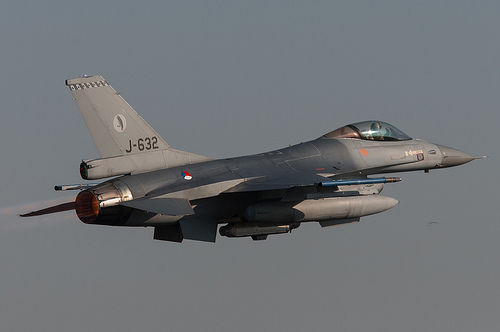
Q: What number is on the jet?
A: J-632.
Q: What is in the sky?
A: A jet.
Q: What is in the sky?
A: A plane.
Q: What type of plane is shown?
A: A military plane.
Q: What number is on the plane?
A: J-632.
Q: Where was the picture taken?
A: The sky.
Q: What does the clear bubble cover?
A: The cockpit.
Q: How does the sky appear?
A: Clear and gray.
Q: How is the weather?
A: Clear.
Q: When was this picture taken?
A: Morning.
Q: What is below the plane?
A: Missiles.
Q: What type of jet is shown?
A: Military.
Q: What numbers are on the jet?
A: 632.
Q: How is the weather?
A: Overcast.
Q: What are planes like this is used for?
A: War.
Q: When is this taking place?
A: Daytime.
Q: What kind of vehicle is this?
A: Airplane.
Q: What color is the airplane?
A: Grey.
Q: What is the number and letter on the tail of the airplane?
A: J-632.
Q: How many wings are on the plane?
A: Two.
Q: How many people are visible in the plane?
A: One.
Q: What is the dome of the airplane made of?
A: Glass.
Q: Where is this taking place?
A: In the sky.